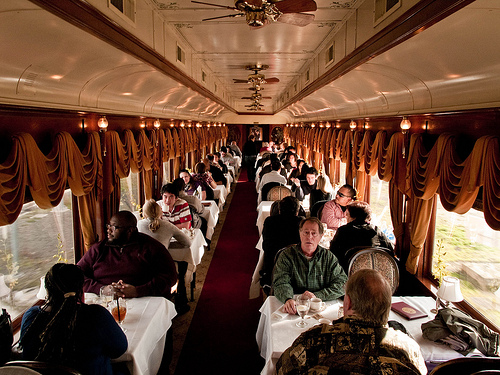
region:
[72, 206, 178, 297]
man sitting at dinning table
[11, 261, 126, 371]
woman sitting at dinning table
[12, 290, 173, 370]
white table cloth covered table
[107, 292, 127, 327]
drink glass on table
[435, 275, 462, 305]
small lamp on table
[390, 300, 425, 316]
dark colored book on table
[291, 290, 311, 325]
clear glass on table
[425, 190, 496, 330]
large glass window next to table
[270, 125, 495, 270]
brown curtains hanging over windows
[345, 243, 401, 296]
empty chair next to window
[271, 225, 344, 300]
Man sitting at table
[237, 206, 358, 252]
White table cloth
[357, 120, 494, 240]
Orange Curtains above windows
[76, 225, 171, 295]
Black man with red shirt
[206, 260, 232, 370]
Burgundy walk way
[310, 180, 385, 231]
Man in red with glasses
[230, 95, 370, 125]
ornate ceiling fan above walls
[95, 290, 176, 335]
Light brown beverage on table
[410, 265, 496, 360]
Jacket on table first table on right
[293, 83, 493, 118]
Reflective white paneling on walls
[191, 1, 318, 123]
The fans on the ceiling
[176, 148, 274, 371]
The aisle down the middle of the tables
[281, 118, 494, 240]
Curtains on the right side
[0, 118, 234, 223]
Curtains down the left side of the train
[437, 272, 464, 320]
Lamp on the table nearest the camera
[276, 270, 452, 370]
Person nearest the camera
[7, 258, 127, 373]
The woman nearest the camera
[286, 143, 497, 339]
The windows on the right side of the train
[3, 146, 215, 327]
The windows on the left side of the train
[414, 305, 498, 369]
Jacket shown on a table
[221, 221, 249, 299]
Carpet is red color.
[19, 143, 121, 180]
window screen is brown color.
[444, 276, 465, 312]
Lamp is white color.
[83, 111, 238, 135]
Lights are on.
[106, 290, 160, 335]
Table cloth is white color.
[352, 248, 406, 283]
Chair is brown color.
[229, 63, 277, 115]
Fan is hanging in the center.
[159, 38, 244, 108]
Ceiling is cream color.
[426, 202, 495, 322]
Sunlight through glass window.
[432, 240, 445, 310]
Flower is in the vase.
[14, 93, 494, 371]
People sitting in a dining hall on a train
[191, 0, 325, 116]
A group of ceiling fans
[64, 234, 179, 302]
A purple sweat shirt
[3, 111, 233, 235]
Gold curtains above the windows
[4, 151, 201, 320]
Multiple glass windows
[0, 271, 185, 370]
A table with a white table cloth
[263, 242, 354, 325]
A green jacket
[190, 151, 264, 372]
Red carpet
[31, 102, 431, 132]
Light fixtures above the windows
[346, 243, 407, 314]
An empty chair